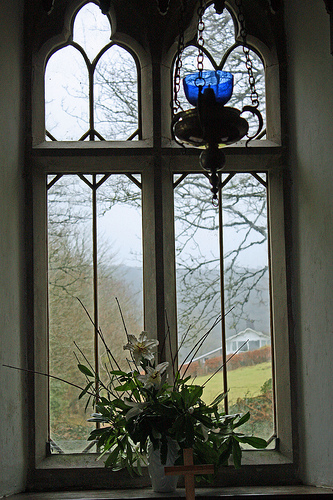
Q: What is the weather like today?
A: It is cloudy.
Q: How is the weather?
A: It is cloudy.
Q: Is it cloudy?
A: Yes, it is cloudy.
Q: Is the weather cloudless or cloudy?
A: It is cloudy.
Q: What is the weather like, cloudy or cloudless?
A: It is cloudy.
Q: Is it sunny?
A: No, it is cloudy.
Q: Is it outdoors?
A: Yes, it is outdoors.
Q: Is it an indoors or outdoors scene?
A: It is outdoors.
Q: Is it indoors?
A: No, it is outdoors.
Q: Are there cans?
A: No, there are no cans.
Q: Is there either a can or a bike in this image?
A: No, there are no cans or bikes.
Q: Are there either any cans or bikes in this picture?
A: No, there are no cans or bikes.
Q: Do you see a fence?
A: No, there are no fences.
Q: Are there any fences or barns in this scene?
A: No, there are no fences or barns.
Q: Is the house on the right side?
A: Yes, the house is on the right of the image.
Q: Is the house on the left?
A: No, the house is on the right of the image.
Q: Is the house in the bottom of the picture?
A: Yes, the house is in the bottom of the image.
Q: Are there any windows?
A: Yes, there is a window.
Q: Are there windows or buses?
A: Yes, there is a window.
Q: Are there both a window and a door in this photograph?
A: No, there is a window but no doors.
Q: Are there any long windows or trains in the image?
A: Yes, there is a long window.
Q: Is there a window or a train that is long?
A: Yes, the window is long.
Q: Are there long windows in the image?
A: Yes, there is a long window.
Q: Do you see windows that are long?
A: Yes, there is a long window.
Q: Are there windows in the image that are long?
A: Yes, there is a window that is long.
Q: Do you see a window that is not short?
A: Yes, there is a long window.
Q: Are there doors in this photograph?
A: No, there are no doors.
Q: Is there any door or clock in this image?
A: No, there are no doors or clocks.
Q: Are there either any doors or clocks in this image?
A: No, there are no doors or clocks.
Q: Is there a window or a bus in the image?
A: Yes, there is a window.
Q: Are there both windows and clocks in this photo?
A: No, there is a window but no clocks.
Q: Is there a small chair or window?
A: Yes, there is a small window.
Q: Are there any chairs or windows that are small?
A: Yes, the window is small.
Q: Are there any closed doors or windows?
A: Yes, there is a closed window.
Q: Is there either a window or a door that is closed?
A: Yes, the window is closed.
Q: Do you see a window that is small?
A: Yes, there is a small window.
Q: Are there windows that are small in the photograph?
A: Yes, there is a small window.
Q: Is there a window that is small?
A: Yes, there is a window that is small.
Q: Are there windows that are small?
A: Yes, there is a window that is small.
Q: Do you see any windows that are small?
A: Yes, there is a window that is small.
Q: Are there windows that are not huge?
A: Yes, there is a small window.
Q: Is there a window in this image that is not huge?
A: Yes, there is a small window.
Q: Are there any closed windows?
A: Yes, there is a closed window.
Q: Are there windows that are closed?
A: Yes, there is a window that is closed.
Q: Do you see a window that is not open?
A: Yes, there is an closed window.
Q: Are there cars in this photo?
A: No, there are no cars.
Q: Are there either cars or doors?
A: No, there are no cars or doors.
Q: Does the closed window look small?
A: Yes, the window is small.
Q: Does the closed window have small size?
A: Yes, the window is small.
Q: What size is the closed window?
A: The window is small.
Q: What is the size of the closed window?
A: The window is small.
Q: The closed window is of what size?
A: The window is small.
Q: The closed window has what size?
A: The window is small.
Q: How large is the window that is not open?
A: The window is small.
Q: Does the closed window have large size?
A: No, the window is small.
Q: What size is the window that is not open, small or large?
A: The window is small.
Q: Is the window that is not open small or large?
A: The window is small.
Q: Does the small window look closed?
A: Yes, the window is closed.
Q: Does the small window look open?
A: No, the window is closed.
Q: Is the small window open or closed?
A: The window is closed.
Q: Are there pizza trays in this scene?
A: No, there are no pizza trays.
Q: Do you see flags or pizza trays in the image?
A: No, there are no pizza trays or flags.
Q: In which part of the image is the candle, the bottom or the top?
A: The candle is in the top of the image.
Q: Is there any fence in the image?
A: No, there are no fences.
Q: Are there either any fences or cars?
A: No, there are no fences or cars.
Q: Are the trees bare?
A: Yes, the trees are bare.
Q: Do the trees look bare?
A: Yes, the trees are bare.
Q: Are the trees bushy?
A: No, the trees are bare.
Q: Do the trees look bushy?
A: No, the trees are bare.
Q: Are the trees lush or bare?
A: The trees are bare.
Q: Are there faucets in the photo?
A: No, there are no faucets.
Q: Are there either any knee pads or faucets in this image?
A: No, there are no faucets or knee pads.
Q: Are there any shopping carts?
A: No, there are no shopping carts.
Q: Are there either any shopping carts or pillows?
A: No, there are no shopping carts or pillows.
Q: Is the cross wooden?
A: Yes, the cross is wooden.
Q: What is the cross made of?
A: The cross is made of wood.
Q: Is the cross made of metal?
A: No, the cross is made of wood.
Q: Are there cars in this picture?
A: No, there are no cars.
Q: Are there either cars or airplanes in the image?
A: No, there are no cars or airplanes.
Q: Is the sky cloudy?
A: Yes, the sky is cloudy.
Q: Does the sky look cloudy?
A: Yes, the sky is cloudy.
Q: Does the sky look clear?
A: No, the sky is cloudy.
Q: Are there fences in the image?
A: No, there are no fences.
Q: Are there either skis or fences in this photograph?
A: No, there are no fences or skis.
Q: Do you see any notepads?
A: No, there are no notepads.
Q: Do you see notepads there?
A: No, there are no notepads.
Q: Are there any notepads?
A: No, there are no notepads.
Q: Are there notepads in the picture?
A: No, there are no notepads.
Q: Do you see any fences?
A: No, there are no fences.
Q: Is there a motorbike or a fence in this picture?
A: No, there are no fences or motorcycles.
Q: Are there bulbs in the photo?
A: No, there are no bulbs.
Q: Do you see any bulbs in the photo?
A: No, there are no bulbs.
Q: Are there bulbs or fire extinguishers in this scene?
A: No, there are no bulbs or fire extinguishers.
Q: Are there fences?
A: No, there are no fences.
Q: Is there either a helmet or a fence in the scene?
A: No, there are no fences or helmets.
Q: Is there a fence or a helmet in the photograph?
A: No, there are no fences or helmets.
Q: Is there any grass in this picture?
A: Yes, there is grass.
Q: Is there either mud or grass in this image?
A: Yes, there is grass.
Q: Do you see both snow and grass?
A: No, there is grass but no snow.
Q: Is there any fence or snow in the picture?
A: No, there are no fences or snow.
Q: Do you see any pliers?
A: No, there are no pliers.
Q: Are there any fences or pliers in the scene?
A: No, there are no pliers or fences.